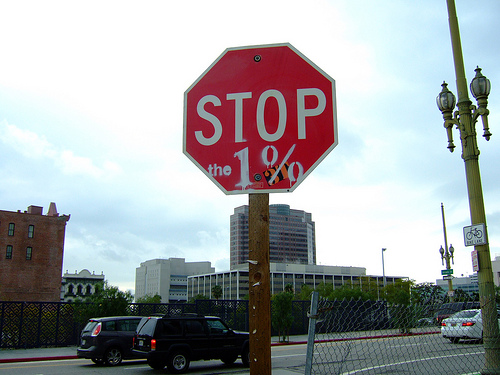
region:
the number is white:
[233, 141, 269, 209]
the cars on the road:
[85, 308, 255, 370]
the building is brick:
[0, 211, 65, 308]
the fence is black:
[232, 299, 379, 329]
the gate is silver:
[330, 302, 482, 363]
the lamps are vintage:
[439, 82, 498, 145]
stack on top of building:
[43, 193, 73, 220]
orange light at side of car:
[143, 335, 165, 354]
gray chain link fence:
[303, 285, 448, 352]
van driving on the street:
[127, 310, 255, 361]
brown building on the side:
[21, 199, 83, 314]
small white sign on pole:
[451, 218, 491, 248]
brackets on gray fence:
[291, 303, 351, 319]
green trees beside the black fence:
[73, 278, 144, 318]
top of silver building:
[293, 255, 378, 276]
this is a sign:
[182, 42, 348, 209]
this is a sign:
[453, 217, 490, 251]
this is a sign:
[463, 239, 483, 277]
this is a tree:
[66, 289, 131, 336]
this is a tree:
[294, 276, 366, 331]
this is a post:
[438, 6, 499, 370]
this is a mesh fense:
[308, 283, 476, 360]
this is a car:
[132, 308, 266, 374]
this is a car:
[77, 303, 162, 365]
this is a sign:
[173, 42, 344, 208]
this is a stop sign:
[160, 30, 336, 205]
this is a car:
[125, 298, 280, 362]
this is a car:
[433, 294, 483, 349]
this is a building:
[0, 202, 116, 329]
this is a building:
[135, 239, 227, 314]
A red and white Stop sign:
[176, 35, 341, 198]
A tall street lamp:
[427, 0, 493, 370]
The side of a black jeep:
[126, 310, 258, 371]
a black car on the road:
[96, 264, 251, 370]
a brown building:
[3, 170, 110, 355]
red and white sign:
[185, 41, 335, 195]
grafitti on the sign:
[238, 136, 300, 191]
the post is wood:
[247, 190, 273, 374]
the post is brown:
[249, 189, 273, 374]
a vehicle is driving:
[138, 307, 252, 374]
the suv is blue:
[81, 316, 142, 367]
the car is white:
[442, 303, 482, 343]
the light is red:
[460, 321, 472, 327]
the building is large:
[230, 200, 325, 272]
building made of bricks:
[0, 201, 68, 303]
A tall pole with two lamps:
[430, 0, 496, 370]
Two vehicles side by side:
[70, 300, 255, 370]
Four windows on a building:
[0, 215, 40, 265]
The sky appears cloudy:
[0, 0, 496, 300]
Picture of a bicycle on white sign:
[455, 216, 490, 248]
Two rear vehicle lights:
[125, 326, 160, 351]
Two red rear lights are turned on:
[431, 311, 476, 327]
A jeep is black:
[125, 310, 255, 370]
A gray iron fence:
[300, 285, 497, 371]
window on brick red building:
[7, 221, 16, 238]